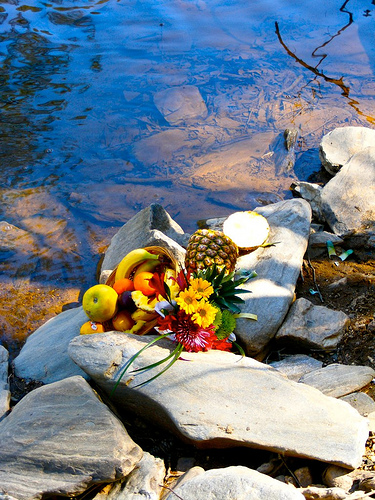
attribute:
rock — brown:
[149, 84, 214, 126]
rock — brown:
[145, 60, 193, 80]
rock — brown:
[130, 133, 206, 168]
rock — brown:
[190, 153, 285, 192]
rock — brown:
[273, 97, 335, 128]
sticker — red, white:
[85, 321, 101, 331]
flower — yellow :
[163, 269, 261, 356]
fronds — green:
[194, 259, 253, 313]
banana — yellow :
[113, 247, 162, 280]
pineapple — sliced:
[166, 226, 238, 286]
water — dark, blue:
[11, 23, 370, 376]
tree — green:
[8, 31, 79, 183]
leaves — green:
[112, 330, 184, 388]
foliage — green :
[106, 330, 182, 390]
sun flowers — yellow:
[167, 278, 216, 321]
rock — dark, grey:
[264, 291, 358, 357]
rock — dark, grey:
[8, 304, 98, 385]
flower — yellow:
[184, 296, 220, 330]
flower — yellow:
[170, 286, 202, 320]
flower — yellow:
[183, 271, 217, 299]